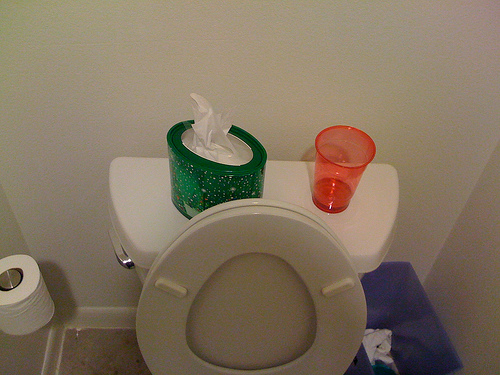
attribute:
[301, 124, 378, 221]
cup — red, plastic, empty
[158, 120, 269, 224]
dispenser — green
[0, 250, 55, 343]
toilet paper — rolled, white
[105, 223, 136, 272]
level — for flushing toilet, chrome, metal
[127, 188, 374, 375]
seat — raised up, white, plastic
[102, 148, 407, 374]
toilet — existing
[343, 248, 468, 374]
waste basket — blue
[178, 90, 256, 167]
tissue paper — small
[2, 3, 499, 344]
wall — painted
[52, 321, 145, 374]
floor — tan colored